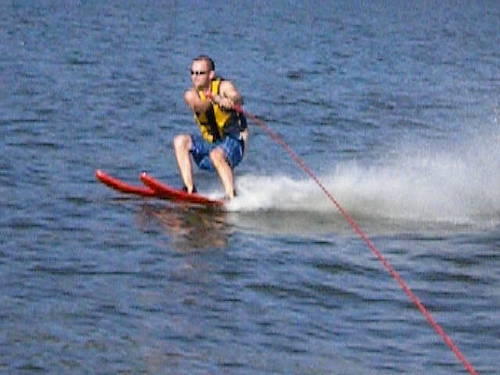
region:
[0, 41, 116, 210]
man water skiing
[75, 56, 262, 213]
young man water skiing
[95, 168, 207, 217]
red water skis used by man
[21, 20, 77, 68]
choppy blue water in lake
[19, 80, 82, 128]
choppy blue water in lake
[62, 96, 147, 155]
choppy blue water in lake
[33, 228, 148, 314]
choppy blue water in lake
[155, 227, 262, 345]
choppy blue water in lake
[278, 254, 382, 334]
choppy blue water in lake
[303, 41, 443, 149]
choppy blue water in lake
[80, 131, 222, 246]
this is a surf board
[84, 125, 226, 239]
the surfboard is red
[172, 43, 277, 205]
the man is surfing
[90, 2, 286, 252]
man on water skies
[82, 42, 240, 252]
man in yellow vest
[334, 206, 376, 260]
thin red rope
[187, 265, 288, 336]
blue ripples on the surface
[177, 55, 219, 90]
sunglasses on a face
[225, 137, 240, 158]
blue plaid short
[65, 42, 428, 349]
man holding a red rope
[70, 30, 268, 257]
man waters skiing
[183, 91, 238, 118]
hand holding rope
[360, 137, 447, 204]
white water in the air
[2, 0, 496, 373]
The water is calm with small ripples.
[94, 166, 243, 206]
Two red water skis are sticking out of the water.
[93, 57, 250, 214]
The man is water skiing.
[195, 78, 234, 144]
The man is wearing a yellow safety vest.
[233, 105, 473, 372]
A red rope goes back to the person.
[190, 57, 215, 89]
The man is wearing sunglasses on his face.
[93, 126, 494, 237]
Spray is coming off of the skis.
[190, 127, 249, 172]
The man is wearing blue and white trunks.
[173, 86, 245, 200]
The man's arms and legs are bent.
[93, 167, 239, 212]
Dark colored water ski boots hold the man on the skis.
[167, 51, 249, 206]
man skiing on red skis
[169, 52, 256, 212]
man holding red rope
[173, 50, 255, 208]
man wearing yellow life vest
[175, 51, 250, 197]
man wearing blue plaid shorts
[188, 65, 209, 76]
sunglasses the man is wearing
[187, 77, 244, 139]
yellow life vest the man is wearing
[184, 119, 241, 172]
blue plaid shorts the man is wearing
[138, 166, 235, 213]
right ski the man is on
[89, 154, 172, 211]
left ski the man is riding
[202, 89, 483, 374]
rope the man is holding